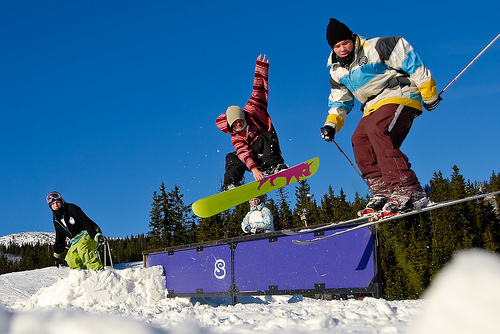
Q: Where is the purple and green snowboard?
A: In air.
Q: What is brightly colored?
A: Snowboard.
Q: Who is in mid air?
A: Man on skis.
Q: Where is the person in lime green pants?
A: On left.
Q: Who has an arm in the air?
A: Man on snowboard.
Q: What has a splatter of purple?
A: Snowboard.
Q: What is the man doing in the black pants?
A: On snowboard.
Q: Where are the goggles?
A: On top of his head.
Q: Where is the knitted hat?
A: Ontop hs head.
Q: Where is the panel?
A: The panel is located on metal legs in the snow.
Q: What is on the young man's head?
A: A gray hoodie.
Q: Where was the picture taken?
A: On a snow slope.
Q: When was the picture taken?
A: During the winter.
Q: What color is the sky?
A: Blue.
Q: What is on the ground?
A: Snow.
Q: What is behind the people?
A: Trees.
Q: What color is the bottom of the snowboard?
A: Green and pink.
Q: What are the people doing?
A: Snowboarding and skiing.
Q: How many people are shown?
A: 4.